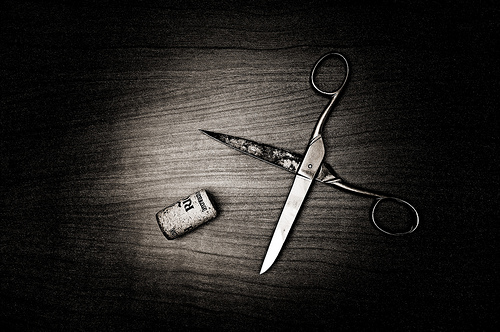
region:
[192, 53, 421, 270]
Scissors open on a table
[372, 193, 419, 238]
Loop handle in scissors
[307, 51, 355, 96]
A loop on a scissors handle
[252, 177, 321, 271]
A blade on one side of scissors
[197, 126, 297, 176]
A dirty blade on scissors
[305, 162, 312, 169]
A small screw connecting scissors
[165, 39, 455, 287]
a pair of scissors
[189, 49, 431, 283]
the scissors are open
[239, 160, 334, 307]
blade of the scissors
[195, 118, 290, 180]
discolored blade of scissors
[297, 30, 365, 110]
right handle of scissors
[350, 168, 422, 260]
left handle of scissors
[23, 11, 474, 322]
scissors on a wooden surface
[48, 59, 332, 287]
the grain of the wood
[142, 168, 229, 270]
object next to scissors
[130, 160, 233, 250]
the object is rectangle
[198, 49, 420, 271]
Scissors on a wooden surface.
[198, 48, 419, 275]
Open scissors on a wooden surface.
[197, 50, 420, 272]
Metal scissors on a wooden surface.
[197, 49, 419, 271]
Metal scissors are open.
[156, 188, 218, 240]
Cork next to scissors.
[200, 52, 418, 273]
Scissors next to cork.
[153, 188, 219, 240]
Cork on a wooden surface.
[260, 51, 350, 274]
Top half of scissors.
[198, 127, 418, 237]
Bottom half of scissors.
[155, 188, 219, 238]
Wine cork between scissor blades.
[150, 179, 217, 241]
Cork on a table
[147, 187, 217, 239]
Cork on a table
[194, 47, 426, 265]
scissors on a table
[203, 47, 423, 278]
scissors on a table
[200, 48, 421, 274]
scissors on a table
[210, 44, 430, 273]
scissors on a table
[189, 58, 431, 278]
scissors on a table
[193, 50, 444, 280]
a pair of scissors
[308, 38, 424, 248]
finger holes on handle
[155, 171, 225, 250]
a round object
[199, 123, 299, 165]
rustic area on scissors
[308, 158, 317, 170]
screw holding scissors together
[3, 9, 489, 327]
a wooden table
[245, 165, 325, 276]
light casting on the scissors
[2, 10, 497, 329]
dark part of area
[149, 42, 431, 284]
things on the table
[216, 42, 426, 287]
The scissors is open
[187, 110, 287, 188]
The left blade is rusted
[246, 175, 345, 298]
the right blade is clean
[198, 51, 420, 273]
the scissors are opened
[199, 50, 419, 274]
the scissors are sharp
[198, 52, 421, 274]
the scissors have finger holes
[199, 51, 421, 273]
the scissors is dirty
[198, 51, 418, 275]
the scissors have a pointy end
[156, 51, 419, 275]
the scissors are next to the cork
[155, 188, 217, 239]
the cork is a cylinder shape